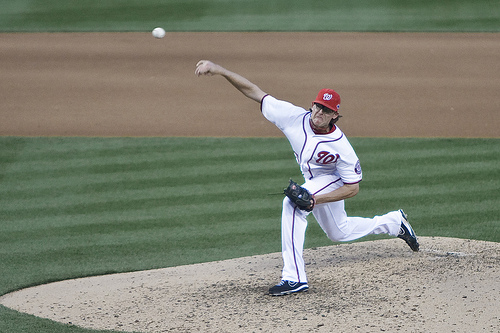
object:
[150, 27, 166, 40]
baseball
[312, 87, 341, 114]
hat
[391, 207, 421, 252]
shoe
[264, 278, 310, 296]
shoe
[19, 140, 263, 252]
turf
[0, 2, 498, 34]
turf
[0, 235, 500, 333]
man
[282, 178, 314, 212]
glove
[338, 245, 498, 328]
mound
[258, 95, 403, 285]
uniform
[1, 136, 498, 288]
grass